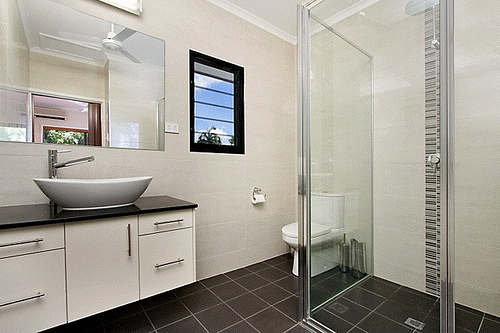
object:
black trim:
[189, 49, 244, 155]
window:
[194, 60, 236, 146]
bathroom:
[0, 0, 499, 332]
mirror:
[0, 0, 168, 151]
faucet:
[47, 149, 95, 179]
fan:
[58, 22, 141, 65]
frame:
[191, 62, 237, 146]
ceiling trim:
[206, 1, 381, 46]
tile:
[138, 249, 358, 331]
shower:
[402, 0, 435, 16]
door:
[294, 0, 459, 332]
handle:
[126, 224, 131, 256]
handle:
[154, 218, 184, 225]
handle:
[154, 258, 184, 268]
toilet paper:
[252, 194, 266, 204]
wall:
[162, 4, 296, 270]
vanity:
[0, 208, 198, 331]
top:
[0, 193, 197, 230]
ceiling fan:
[62, 24, 144, 67]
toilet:
[281, 191, 345, 276]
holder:
[253, 187, 267, 199]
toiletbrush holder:
[339, 233, 350, 273]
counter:
[0, 195, 199, 231]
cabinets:
[0, 194, 198, 332]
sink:
[30, 175, 153, 211]